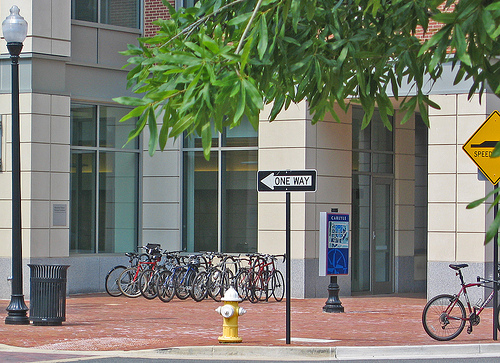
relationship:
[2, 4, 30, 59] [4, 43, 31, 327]
light on pole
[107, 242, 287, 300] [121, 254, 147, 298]
group of bike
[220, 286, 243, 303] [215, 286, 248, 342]
top of hydrant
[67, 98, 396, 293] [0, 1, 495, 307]
windows on building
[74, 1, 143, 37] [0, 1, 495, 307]
windows on building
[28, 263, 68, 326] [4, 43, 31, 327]
trashcan next to pole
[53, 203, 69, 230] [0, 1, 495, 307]
sign on building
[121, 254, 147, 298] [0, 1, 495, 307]
bike outside building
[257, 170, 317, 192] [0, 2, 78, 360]
sign pointing left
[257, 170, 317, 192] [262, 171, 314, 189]
sign with arrow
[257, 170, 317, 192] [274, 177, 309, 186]
sign says one way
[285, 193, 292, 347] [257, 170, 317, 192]
pole for sign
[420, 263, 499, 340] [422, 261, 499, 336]
bicycle by itself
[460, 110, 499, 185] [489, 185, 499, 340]
sign on post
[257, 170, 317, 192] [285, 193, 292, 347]
sign on post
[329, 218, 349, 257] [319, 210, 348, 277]
advertisement on sign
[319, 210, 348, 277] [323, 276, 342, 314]
sign on post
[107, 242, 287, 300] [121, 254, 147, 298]
bunch of bike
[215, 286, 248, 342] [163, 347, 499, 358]
hydrant at curb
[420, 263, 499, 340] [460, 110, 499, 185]
bike to sign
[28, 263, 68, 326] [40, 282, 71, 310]
container for trash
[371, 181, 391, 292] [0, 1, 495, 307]
door into building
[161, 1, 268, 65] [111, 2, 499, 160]
branch with leaves